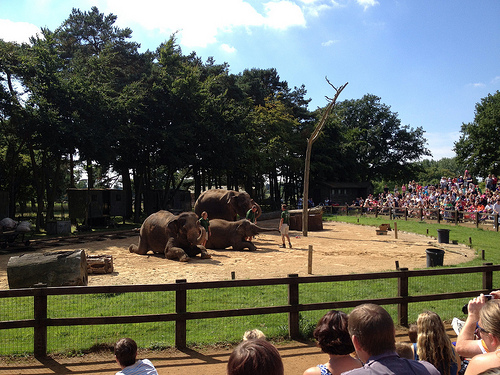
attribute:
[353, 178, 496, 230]
spectators — in the picture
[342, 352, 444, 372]
shirt — blue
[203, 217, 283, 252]
elephant — Grey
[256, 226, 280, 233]
trunk — Grey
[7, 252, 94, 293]
log — Wood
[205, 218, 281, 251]
middle elephant — Gray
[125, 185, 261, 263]
elephants — in the picture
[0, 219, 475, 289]
dirt area — Brown 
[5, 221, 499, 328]
grass — Green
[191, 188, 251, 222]
elephant — Grey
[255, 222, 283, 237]
trunk — in the picture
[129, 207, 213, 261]
elephant — Grey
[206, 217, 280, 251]
elephant — Gray, Grey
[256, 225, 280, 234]
trunk — stretched out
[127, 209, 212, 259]
elephant — Gray, Grey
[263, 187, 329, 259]
person — Watching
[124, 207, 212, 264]
elephant — Gray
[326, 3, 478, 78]
sky zoo — Blue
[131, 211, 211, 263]
elephant — kneeling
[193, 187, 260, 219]
elephant — Gray, Grey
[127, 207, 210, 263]
elephants — Gray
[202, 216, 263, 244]
elephants — Gray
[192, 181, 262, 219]
elephants — Gray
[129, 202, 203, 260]
elephant — Grey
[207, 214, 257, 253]
elephant — Grey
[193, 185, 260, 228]
elephant — Grey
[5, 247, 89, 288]
log — Wooden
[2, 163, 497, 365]
enclosure — Large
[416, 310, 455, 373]
hair — wavy, blonde, light brown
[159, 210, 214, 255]
elephant — Grey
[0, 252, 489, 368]
fence — brown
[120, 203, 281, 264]
elephants — in the picture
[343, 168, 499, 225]
people — Watching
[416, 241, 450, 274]
can — green, trash